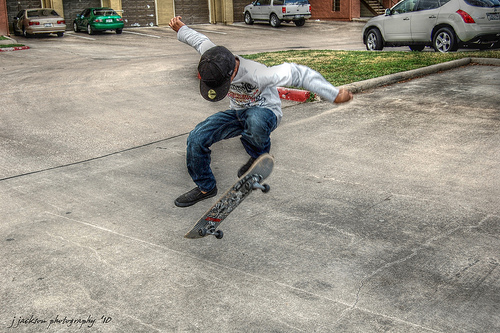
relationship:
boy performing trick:
[165, 14, 354, 208] [162, 134, 326, 238]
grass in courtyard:
[313, 53, 405, 68] [13, 31, 495, 329]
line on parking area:
[66, 32, 95, 41] [8, 19, 412, 55]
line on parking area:
[123, 28, 160, 38] [8, 19, 412, 55]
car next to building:
[75, 10, 128, 41] [17, 0, 361, 39]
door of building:
[117, 0, 157, 27] [0, 0, 356, 36]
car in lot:
[362, 0, 500, 56] [0, 7, 499, 164]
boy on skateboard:
[165, 14, 354, 208] [183, 150, 274, 239]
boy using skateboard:
[165, 14, 354, 208] [178, 148, 295, 255]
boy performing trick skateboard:
[149, 8, 366, 278] [173, 145, 293, 244]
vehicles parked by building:
[13, 4, 67, 36] [0, 0, 390, 33]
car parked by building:
[71, 9, 126, 37] [0, 0, 390, 33]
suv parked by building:
[240, 0, 317, 30] [0, 0, 390, 33]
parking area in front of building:
[32, 28, 412, 55] [5, 1, 385, 29]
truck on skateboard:
[198, 219, 225, 246] [181, 145, 280, 245]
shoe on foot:
[173, 182, 217, 209] [175, 185, 215, 207]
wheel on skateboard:
[194, 225, 225, 242] [182, 153, 278, 246]